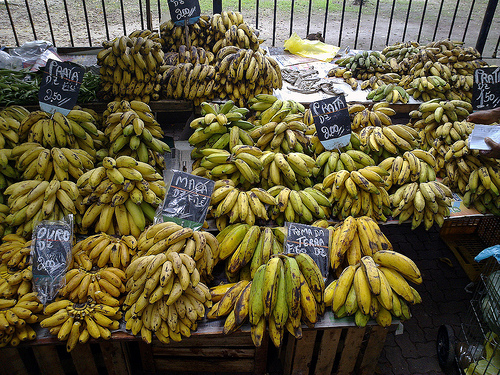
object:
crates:
[286, 328, 388, 371]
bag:
[282, 30, 341, 63]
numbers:
[309, 91, 352, 150]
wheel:
[437, 316, 456, 370]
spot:
[160, 265, 172, 281]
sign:
[309, 94, 350, 152]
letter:
[312, 100, 322, 119]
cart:
[434, 235, 498, 375]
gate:
[1, 0, 499, 52]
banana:
[233, 158, 256, 185]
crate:
[348, 328, 386, 375]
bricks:
[393, 335, 418, 362]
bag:
[13, 47, 45, 65]